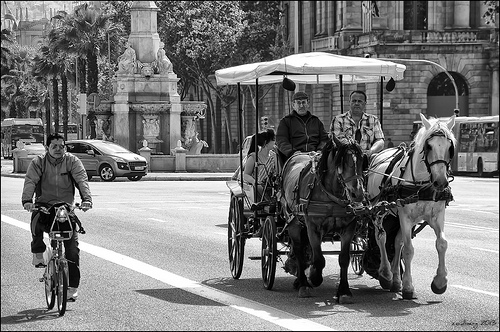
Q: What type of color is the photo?
A: Black and white.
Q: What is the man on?
A: Bike.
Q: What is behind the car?
A: Trees.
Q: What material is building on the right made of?
A: Brick.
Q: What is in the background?
A: Statue.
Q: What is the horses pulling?
A: Cart.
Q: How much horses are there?
A: 2.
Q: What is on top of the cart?
A: Canopy.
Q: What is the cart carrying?
A: Goods.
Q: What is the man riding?
A: A bicycle.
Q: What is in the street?
A: A vehicle.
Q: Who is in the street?
A: A person.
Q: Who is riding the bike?
A: A guy.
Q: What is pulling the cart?
A: Two horses.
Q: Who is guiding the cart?
A: Two men.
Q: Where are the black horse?
A: Alongside the white horse.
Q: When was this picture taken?
A: Daytime.